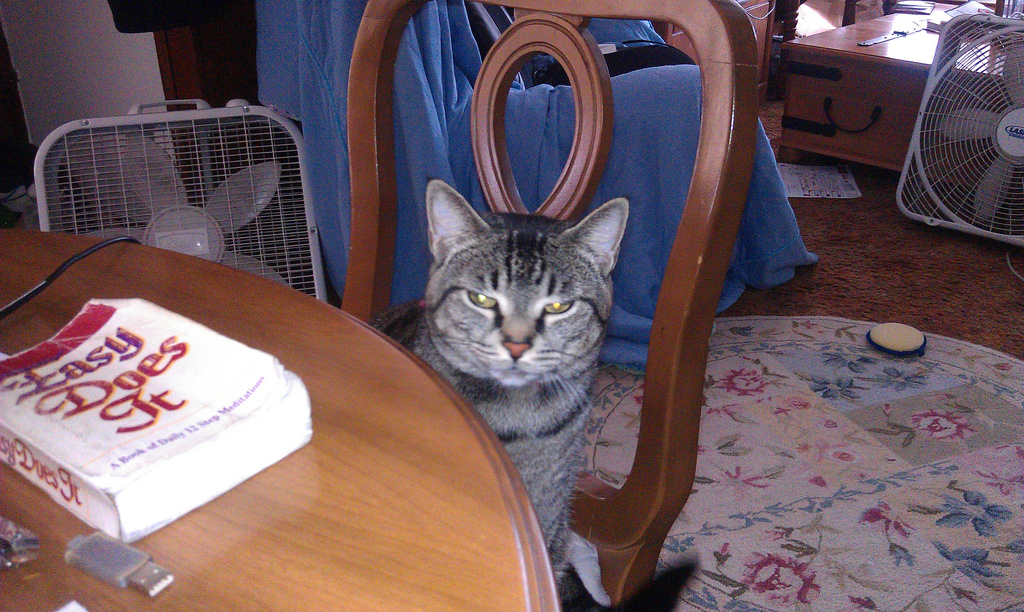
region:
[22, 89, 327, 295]
box fan behind table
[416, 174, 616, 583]
grey and black cat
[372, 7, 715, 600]
Tabby cat sitting on a chair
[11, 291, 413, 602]
A book and a flash drive on a table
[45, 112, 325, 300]
A dirty fan on the floor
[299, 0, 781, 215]
a covered piece of furniture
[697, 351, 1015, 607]
partial area rug on the floor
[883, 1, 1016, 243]
Half of a bigger fan on the floor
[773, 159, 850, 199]
a piece of paper on the floor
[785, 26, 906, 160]
A handle of a coffee table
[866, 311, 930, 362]
A small tamborine on the area rug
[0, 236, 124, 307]
A cord to something sitting on the table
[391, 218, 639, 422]
a cat is sleepy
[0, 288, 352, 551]
someone is reading Easy Does It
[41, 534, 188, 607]
A flashdrive is on the table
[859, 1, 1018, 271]
The fan is not running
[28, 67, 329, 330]
The fan is not running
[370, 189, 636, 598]
The cat is striped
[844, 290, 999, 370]
There is something sitting on the rug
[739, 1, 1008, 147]
The sun is shining through windows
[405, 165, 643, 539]
The cat is not entertained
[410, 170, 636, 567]
A furry gray cat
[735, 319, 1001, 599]
An area rug has many colors on it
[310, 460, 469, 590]
The wooden table is brown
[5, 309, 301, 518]
A book has red and white on the cover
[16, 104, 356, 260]
A white fan is on the floor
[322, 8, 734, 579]
The chair is brown and wooden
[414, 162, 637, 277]
Ears on a cat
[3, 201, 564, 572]
The table is round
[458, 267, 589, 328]
Eyes on a cat are yellow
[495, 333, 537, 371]
The nose on a cat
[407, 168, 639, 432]
is this a cat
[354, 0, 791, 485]
cat on a chair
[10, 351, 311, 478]
book on a table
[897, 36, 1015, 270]
fan on the floor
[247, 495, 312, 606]
wooden table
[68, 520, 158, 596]
computer jump drive on a table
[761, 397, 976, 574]
floral carpet on the floor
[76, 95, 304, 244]
box fan on the floor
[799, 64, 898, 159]
handle on a box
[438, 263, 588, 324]
yellow cats eyes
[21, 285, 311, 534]
A book is on a table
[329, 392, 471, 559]
A brown wooden table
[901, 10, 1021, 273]
A white fan on the floor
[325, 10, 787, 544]
A brown wooden chair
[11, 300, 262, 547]
The book's cover is white and red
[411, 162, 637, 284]
The cat has pointy ears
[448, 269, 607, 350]
A cat has yellow eyes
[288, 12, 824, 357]
A couch has a blue covering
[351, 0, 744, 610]
a cat sitting on a wooden chair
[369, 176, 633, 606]
a gray cat sitting on a chair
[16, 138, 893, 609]
a cat is sitting on a table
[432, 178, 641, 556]
Gray cat with green eyes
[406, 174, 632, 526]
An angry looking cat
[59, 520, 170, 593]
A usb flash drive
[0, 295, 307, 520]
A book called Easy Does It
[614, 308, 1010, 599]
A rug with flower patterns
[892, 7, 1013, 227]
A box fan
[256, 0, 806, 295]
A chair covered in a blue blanket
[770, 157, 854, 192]
A piece of paper on the floor